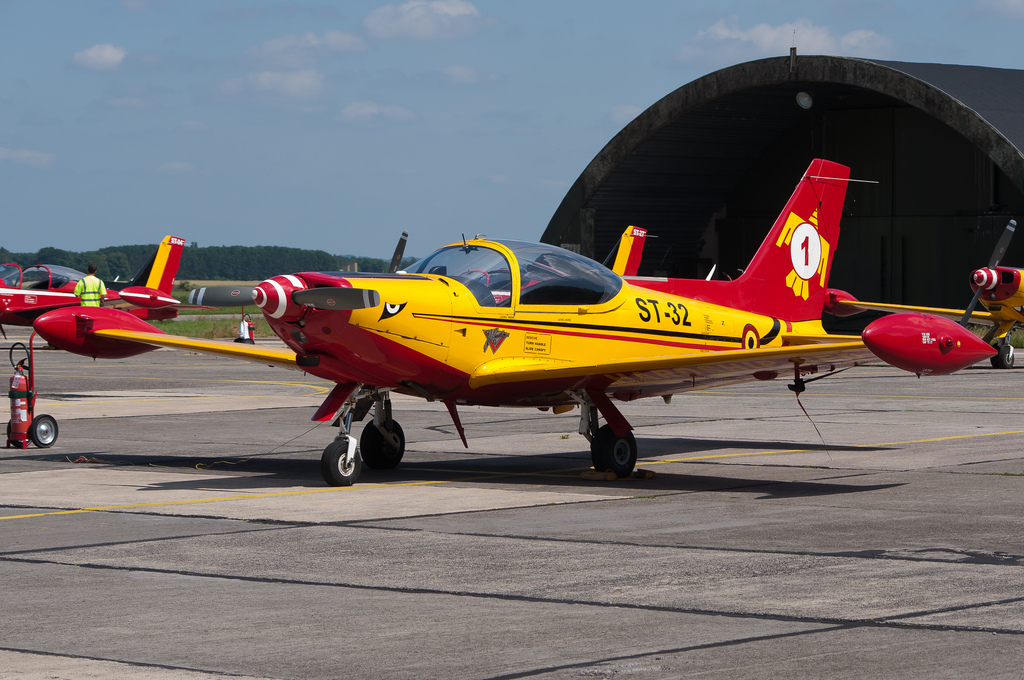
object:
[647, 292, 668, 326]
letter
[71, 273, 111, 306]
jacket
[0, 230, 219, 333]
airplane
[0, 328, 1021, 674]
airport tarmac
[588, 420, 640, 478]
airplane tire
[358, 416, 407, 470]
airplane tire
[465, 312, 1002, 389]
airplane wing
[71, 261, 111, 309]
man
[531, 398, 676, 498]
tire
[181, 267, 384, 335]
propeller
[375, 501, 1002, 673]
road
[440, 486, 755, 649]
floor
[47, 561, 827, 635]
lines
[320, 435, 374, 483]
wheel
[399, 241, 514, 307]
glasses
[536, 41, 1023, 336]
building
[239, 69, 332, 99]
clouds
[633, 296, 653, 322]
letter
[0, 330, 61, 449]
fire extinguisher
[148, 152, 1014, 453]
airplane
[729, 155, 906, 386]
tail